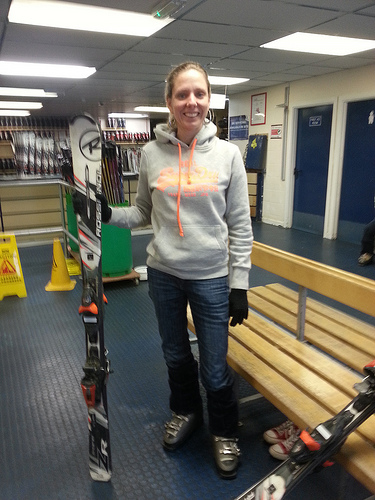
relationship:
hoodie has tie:
[100, 126, 270, 288] [168, 137, 201, 251]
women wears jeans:
[94, 54, 267, 482] [139, 258, 251, 444]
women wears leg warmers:
[94, 54, 267, 482] [164, 362, 247, 440]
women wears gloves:
[94, 54, 267, 482] [225, 285, 252, 328]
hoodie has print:
[100, 126, 270, 288] [147, 164, 225, 203]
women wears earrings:
[94, 54, 267, 482] [203, 103, 217, 122]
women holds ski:
[94, 54, 267, 482] [59, 111, 135, 500]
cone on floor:
[42, 236, 80, 298] [3, 218, 375, 500]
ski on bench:
[228, 357, 374, 499] [230, 236, 373, 495]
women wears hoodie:
[94, 54, 267, 482] [100, 126, 270, 288]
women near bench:
[94, 54, 267, 482] [230, 236, 373, 495]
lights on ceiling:
[3, 1, 194, 46] [3, 1, 374, 136]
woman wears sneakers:
[94, 54, 267, 482] [210, 410, 242, 476]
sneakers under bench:
[263, 413, 310, 465] [230, 236, 373, 495]